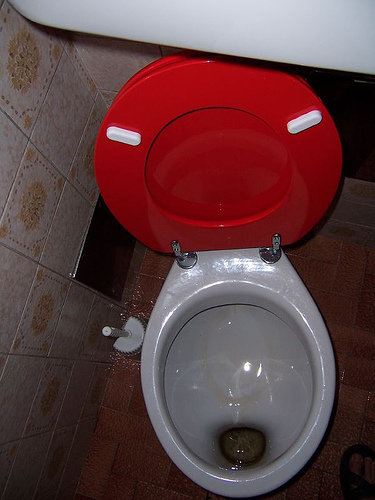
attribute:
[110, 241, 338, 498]
toilet — porcelain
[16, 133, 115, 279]
ceramic tile — brown , white 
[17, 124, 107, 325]
wall — tiled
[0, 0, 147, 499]
wall — orange, white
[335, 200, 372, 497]
floor — brown, tiled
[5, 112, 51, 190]
tile — brown , white 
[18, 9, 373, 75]
top — counter, white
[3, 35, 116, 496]
tile — brown , white 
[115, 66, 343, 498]
toilet — dirty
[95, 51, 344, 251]
lid — toilet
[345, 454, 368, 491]
sandals — black, pictured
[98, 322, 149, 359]
brush — white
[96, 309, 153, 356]
brush — white, toilet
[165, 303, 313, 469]
toilet bowl — white 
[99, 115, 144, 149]
white stopper — left side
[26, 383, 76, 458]
tile — ceramic, brown, white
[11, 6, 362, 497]
restroom — pictured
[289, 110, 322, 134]
stopper — right side, white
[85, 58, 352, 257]
lid — toilet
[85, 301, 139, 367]
plunger — white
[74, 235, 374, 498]
tiles — reddish brown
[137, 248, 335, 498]
bowl — white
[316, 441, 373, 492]
shoe — black, sandal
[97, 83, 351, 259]
toilet seat — red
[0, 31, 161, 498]
tile — white , brown 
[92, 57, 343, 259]
toilet seat — bright red, red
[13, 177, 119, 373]
wall — tiled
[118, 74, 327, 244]
lid — red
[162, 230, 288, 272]
hinges — silver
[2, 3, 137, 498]
tile wall — tan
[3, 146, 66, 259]
brown tile — white, ceramic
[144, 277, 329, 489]
bowl — toilet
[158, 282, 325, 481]
toilet bowl — pictured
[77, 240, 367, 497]
linoleum — red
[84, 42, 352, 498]
toilet — white, brown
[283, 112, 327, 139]
piece — white